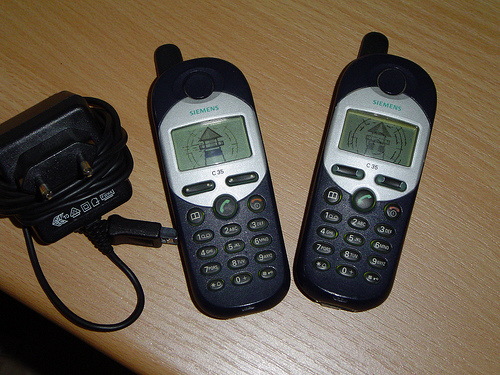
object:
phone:
[293, 32, 439, 313]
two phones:
[145, 31, 436, 320]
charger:
[0, 90, 181, 333]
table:
[0, 0, 500, 374]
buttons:
[354, 187, 374, 210]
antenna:
[357, 31, 390, 56]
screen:
[337, 108, 418, 168]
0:
[341, 265, 349, 274]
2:
[349, 217, 359, 224]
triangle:
[368, 121, 392, 139]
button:
[385, 206, 402, 221]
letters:
[371, 98, 376, 106]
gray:
[347, 95, 371, 106]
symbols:
[50, 212, 70, 227]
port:
[317, 299, 356, 314]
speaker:
[376, 72, 406, 96]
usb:
[158, 225, 179, 246]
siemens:
[189, 105, 219, 116]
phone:
[146, 44, 290, 320]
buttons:
[214, 197, 238, 220]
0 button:
[231, 272, 251, 284]